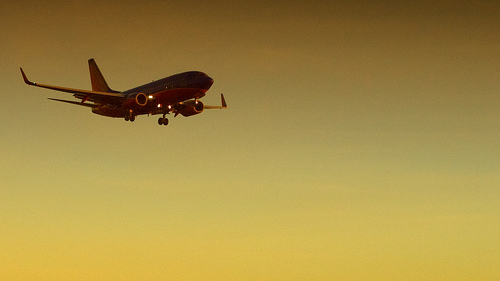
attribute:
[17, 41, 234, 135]
airplane — flying, passenger, here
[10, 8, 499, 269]
sky — yellow, sunny, blue, yellowish, dark,  taken outside., brown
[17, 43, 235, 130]
jetliner — conmmercial, flying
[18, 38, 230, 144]
plane — flying, passenger, blue, landing, took off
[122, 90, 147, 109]
engine — here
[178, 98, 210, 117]
engine — here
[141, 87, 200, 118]
lights — on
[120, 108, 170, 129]
wheels — black, down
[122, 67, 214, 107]
body — red, blue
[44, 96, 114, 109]
flap — down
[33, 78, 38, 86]
light — on